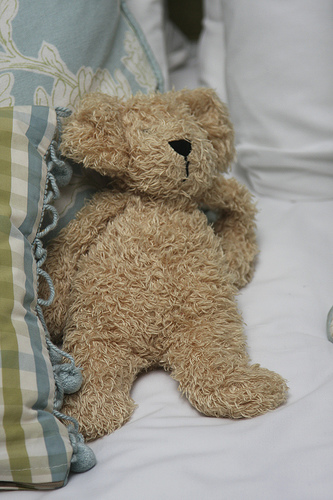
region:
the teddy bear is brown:
[26, 106, 226, 386]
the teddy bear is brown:
[73, 131, 298, 309]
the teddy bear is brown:
[69, 34, 235, 266]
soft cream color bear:
[56, 59, 304, 433]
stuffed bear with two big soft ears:
[29, 61, 327, 432]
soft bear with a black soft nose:
[52, 56, 263, 468]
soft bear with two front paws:
[12, 65, 269, 331]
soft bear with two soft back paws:
[49, 100, 263, 471]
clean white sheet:
[117, 31, 315, 477]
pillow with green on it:
[0, 92, 84, 391]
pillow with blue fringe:
[0, 98, 83, 391]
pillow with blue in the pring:
[0, 236, 102, 493]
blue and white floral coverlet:
[4, 36, 181, 109]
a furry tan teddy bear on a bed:
[40, 90, 288, 439]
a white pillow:
[204, 2, 331, 175]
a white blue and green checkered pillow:
[0, 109, 69, 488]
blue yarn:
[55, 407, 81, 431]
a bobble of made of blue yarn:
[57, 365, 84, 392]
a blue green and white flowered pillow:
[1, 1, 155, 97]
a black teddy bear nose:
[168, 140, 195, 156]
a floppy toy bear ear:
[185, 89, 232, 165]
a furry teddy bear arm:
[202, 176, 263, 281]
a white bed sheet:
[225, 202, 331, 499]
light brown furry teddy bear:
[36, 85, 298, 425]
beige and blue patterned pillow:
[11, 412, 61, 473]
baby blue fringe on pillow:
[51, 411, 99, 473]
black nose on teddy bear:
[155, 132, 201, 192]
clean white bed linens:
[265, 91, 319, 277]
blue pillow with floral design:
[14, 6, 73, 95]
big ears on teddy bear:
[63, 83, 153, 188]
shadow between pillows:
[152, 2, 231, 70]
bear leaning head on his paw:
[154, 92, 265, 300]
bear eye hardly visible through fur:
[131, 117, 161, 143]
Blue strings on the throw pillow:
[47, 149, 97, 471]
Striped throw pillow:
[0, 104, 56, 483]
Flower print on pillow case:
[1, 0, 113, 98]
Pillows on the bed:
[0, 2, 330, 83]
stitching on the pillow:
[4, 461, 65, 477]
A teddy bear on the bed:
[35, 4, 301, 467]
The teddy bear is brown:
[36, 88, 291, 442]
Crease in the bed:
[121, 412, 332, 475]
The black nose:
[168, 135, 198, 155]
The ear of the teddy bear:
[62, 82, 135, 187]